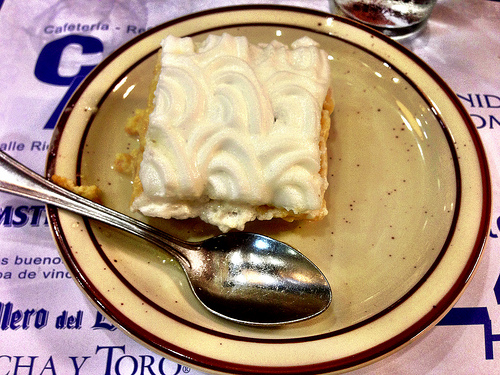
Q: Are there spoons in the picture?
A: Yes, there is a spoon.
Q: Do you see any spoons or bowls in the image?
A: Yes, there is a spoon.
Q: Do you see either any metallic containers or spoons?
A: Yes, there is a metal spoon.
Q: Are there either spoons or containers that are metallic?
A: Yes, the spoon is metallic.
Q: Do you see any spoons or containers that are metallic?
A: Yes, the spoon is metallic.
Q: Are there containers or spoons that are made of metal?
A: Yes, the spoon is made of metal.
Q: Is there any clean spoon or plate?
A: Yes, there is a clean spoon.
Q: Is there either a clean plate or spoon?
A: Yes, there is a clean spoon.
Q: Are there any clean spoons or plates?
A: Yes, there is a clean spoon.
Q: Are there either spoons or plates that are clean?
A: Yes, the spoon is clean.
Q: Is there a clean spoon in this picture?
A: Yes, there is a clean spoon.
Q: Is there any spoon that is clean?
A: Yes, there is a spoon that is clean.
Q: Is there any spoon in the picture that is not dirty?
A: Yes, there is a clean spoon.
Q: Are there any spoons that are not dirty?
A: Yes, there is a clean spoon.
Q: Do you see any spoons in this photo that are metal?
A: Yes, there is a metal spoon.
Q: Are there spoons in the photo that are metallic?
A: Yes, there is a spoon that is metallic.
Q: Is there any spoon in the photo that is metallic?
A: Yes, there is a spoon that is metallic.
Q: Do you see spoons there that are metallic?
A: Yes, there is a spoon that is metallic.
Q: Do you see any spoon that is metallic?
A: Yes, there is a spoon that is metallic.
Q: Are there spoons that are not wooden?
A: Yes, there is a metallic spoon.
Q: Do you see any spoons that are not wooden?
A: Yes, there is a metallic spoon.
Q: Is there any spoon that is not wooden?
A: Yes, there is a metallic spoon.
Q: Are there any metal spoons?
A: Yes, there is a spoon that is made of metal.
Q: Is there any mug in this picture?
A: No, there are no mugs.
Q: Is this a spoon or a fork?
A: This is a spoon.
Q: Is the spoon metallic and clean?
A: Yes, the spoon is metallic and clean.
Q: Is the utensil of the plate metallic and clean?
A: Yes, the spoon is metallic and clean.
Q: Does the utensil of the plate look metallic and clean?
A: Yes, the spoon is metallic and clean.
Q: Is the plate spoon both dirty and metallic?
A: No, the spoon is metallic but clean.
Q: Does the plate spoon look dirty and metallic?
A: No, the spoon is metallic but clean.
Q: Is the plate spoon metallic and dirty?
A: No, the spoon is metallic but clean.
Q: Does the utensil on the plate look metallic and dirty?
A: No, the spoon is metallic but clean.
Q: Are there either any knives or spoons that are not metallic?
A: No, there is a spoon but it is metallic.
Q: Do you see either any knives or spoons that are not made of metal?
A: No, there is a spoon but it is made of metal.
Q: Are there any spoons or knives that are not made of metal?
A: No, there is a spoon but it is made of metal.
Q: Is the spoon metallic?
A: Yes, the spoon is metallic.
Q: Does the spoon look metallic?
A: Yes, the spoon is metallic.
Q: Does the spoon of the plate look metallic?
A: Yes, the spoon is metallic.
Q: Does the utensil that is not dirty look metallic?
A: Yes, the spoon is metallic.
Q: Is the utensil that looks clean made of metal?
A: Yes, the spoon is made of metal.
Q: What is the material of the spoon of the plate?
A: The spoon is made of metal.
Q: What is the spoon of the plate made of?
A: The spoon is made of metal.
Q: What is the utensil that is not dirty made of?
A: The spoon is made of metal.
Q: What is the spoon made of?
A: The spoon is made of metal.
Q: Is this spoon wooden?
A: No, the spoon is metallic.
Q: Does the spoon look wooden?
A: No, the spoon is metallic.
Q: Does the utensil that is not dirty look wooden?
A: No, the spoon is metallic.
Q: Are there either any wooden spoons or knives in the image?
A: No, there is a spoon but it is metallic.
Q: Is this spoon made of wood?
A: No, the spoon is made of metal.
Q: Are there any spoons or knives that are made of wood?
A: No, there is a spoon but it is made of metal.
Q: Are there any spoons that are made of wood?
A: No, there is a spoon but it is made of metal.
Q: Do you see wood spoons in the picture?
A: No, there is a spoon but it is made of metal.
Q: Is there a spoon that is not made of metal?
A: No, there is a spoon but it is made of metal.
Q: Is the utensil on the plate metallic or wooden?
A: The spoon is metallic.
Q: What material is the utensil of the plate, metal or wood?
A: The spoon is made of metal.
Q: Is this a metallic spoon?
A: Yes, this is a metallic spoon.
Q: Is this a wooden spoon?
A: No, this is a metallic spoon.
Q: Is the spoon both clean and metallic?
A: Yes, the spoon is clean and metallic.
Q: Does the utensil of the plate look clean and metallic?
A: Yes, the spoon is clean and metallic.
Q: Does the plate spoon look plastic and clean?
A: No, the spoon is clean but metallic.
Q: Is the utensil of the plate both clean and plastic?
A: No, the spoon is clean but metallic.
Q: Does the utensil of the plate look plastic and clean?
A: No, the spoon is clean but metallic.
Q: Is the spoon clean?
A: Yes, the spoon is clean.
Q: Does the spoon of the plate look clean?
A: Yes, the spoon is clean.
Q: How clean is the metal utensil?
A: The spoon is clean.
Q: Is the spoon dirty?
A: No, the spoon is clean.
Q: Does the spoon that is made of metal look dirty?
A: No, the spoon is clean.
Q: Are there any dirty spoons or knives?
A: No, there is a spoon but it is clean.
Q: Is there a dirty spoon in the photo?
A: No, there is a spoon but it is clean.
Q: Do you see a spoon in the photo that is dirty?
A: No, there is a spoon but it is clean.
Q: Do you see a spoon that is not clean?
A: No, there is a spoon but it is clean.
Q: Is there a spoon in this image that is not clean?
A: No, there is a spoon but it is clean.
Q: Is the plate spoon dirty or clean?
A: The spoon is clean.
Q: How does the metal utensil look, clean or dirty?
A: The spoon is clean.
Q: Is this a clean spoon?
A: Yes, this is a clean spoon.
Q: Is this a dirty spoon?
A: No, this is a clean spoon.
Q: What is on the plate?
A: The spoon is on the plate.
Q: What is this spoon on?
A: The spoon is on the plate.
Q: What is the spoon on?
A: The spoon is on the plate.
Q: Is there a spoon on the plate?
A: Yes, there is a spoon on the plate.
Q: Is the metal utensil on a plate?
A: Yes, the spoon is on a plate.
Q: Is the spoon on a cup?
A: No, the spoon is on a plate.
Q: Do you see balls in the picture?
A: No, there are no balls.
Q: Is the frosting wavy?
A: Yes, the frosting is wavy.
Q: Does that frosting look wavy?
A: Yes, the frosting is wavy.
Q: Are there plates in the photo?
A: Yes, there is a plate.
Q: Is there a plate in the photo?
A: Yes, there is a plate.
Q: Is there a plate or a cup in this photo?
A: Yes, there is a plate.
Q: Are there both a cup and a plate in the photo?
A: No, there is a plate but no cups.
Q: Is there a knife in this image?
A: No, there are no knives.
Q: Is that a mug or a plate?
A: That is a plate.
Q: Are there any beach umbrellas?
A: No, there are no beach umbrellas.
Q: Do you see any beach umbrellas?
A: No, there are no beach umbrellas.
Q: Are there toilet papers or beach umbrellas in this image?
A: No, there are no beach umbrellas or toilet papers.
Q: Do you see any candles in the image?
A: No, there are no candles.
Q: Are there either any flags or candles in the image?
A: No, there are no candles or flags.